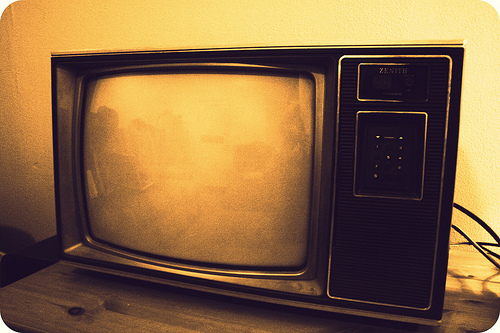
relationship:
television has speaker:
[47, 38, 470, 333] [329, 198, 432, 306]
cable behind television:
[453, 202, 500, 245] [47, 38, 470, 333]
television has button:
[47, 38, 470, 333] [371, 133, 382, 151]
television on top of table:
[47, 38, 470, 333] [2, 249, 499, 333]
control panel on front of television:
[347, 109, 428, 202] [47, 38, 470, 333]